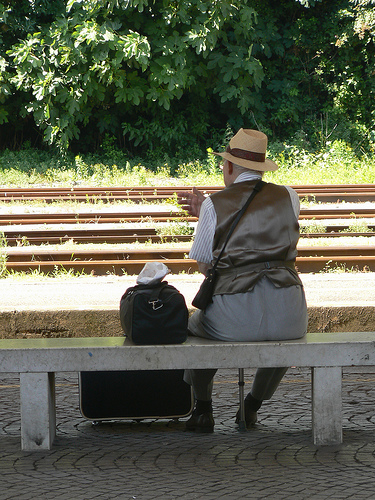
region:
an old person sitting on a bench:
[178, 138, 313, 447]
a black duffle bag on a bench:
[117, 278, 193, 355]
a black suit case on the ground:
[68, 353, 198, 426]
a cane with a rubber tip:
[226, 356, 253, 433]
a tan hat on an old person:
[211, 125, 283, 176]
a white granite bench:
[12, 325, 363, 451]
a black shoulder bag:
[186, 247, 243, 330]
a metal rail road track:
[1, 234, 364, 274]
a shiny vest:
[203, 170, 305, 295]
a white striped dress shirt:
[187, 165, 307, 282]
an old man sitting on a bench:
[166, 119, 318, 447]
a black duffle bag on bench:
[113, 273, 192, 348]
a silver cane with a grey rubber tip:
[230, 357, 256, 433]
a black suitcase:
[69, 356, 199, 436]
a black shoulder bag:
[187, 170, 271, 341]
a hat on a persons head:
[214, 122, 281, 178]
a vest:
[201, 168, 311, 301]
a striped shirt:
[194, 160, 318, 280]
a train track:
[0, 230, 371, 279]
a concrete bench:
[3, 329, 373, 453]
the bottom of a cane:
[235, 369, 245, 432]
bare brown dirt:
[0, 305, 374, 339]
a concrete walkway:
[1, 366, 373, 498]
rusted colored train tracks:
[1, 182, 373, 274]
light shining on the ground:
[1, 187, 374, 312]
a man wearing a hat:
[177, 127, 302, 341]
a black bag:
[119, 284, 188, 342]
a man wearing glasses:
[177, 128, 308, 430]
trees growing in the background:
[0, 0, 374, 154]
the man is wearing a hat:
[174, 112, 306, 206]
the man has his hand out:
[172, 125, 318, 248]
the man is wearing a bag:
[174, 118, 313, 315]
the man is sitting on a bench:
[183, 122, 338, 345]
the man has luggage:
[112, 267, 196, 350]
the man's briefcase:
[70, 344, 199, 430]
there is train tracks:
[53, 180, 151, 266]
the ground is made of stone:
[106, 430, 302, 498]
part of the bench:
[8, 302, 85, 442]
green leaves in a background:
[51, 85, 184, 225]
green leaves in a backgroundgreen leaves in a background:
[264, 33, 330, 111]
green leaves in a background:
[111, 81, 195, 142]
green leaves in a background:
[314, 133, 344, 177]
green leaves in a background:
[32, 65, 155, 156]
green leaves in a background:
[92, 71, 185, 134]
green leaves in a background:
[306, 88, 361, 178]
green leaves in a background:
[18, 48, 106, 184]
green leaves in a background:
[96, 58, 235, 192]